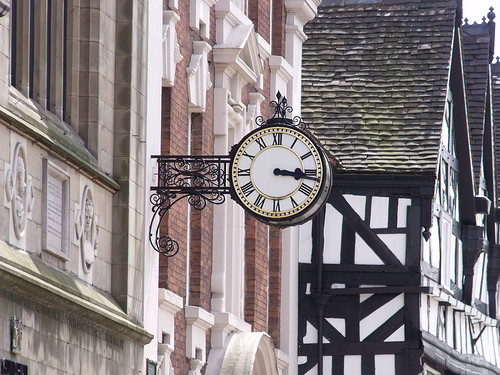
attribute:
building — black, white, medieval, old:
[299, 1, 500, 375]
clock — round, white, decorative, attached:
[230, 123, 333, 226]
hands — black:
[273, 167, 322, 181]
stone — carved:
[0, 0, 154, 374]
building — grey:
[0, 1, 154, 374]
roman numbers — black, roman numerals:
[238, 133, 318, 212]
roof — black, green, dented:
[301, 0, 499, 209]